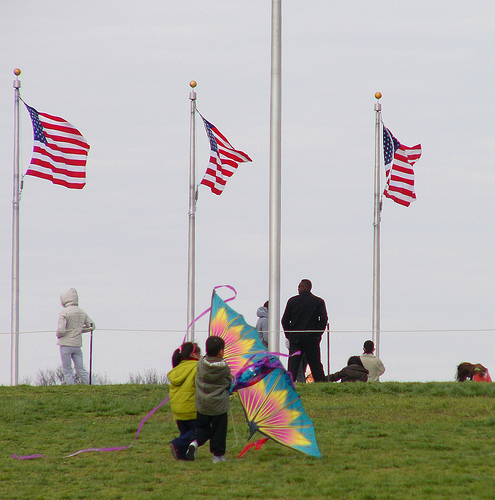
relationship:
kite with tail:
[210, 280, 330, 459] [9, 284, 238, 462]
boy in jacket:
[186, 335, 236, 468] [172, 283, 257, 418]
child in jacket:
[166, 342, 202, 460] [199, 360, 228, 430]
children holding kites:
[166, 335, 233, 465] [203, 300, 331, 461]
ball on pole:
[9, 65, 26, 79] [3, 79, 30, 383]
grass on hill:
[2, 386, 494, 498] [7, 380, 492, 497]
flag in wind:
[380, 119, 422, 208] [7, 59, 439, 223]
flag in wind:
[194, 108, 255, 196] [7, 59, 439, 223]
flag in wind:
[23, 104, 90, 189] [7, 59, 439, 223]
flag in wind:
[371, 116, 425, 208] [336, 73, 430, 234]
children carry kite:
[166, 335, 233, 465] [205, 289, 334, 458]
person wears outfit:
[43, 287, 105, 382] [53, 286, 98, 379]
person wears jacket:
[281, 279, 329, 381] [281, 295, 326, 339]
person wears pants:
[281, 279, 329, 381] [287, 330, 323, 379]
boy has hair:
[186, 335, 232, 463] [205, 337, 223, 356]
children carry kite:
[166, 335, 233, 465] [207, 271, 323, 456]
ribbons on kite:
[231, 344, 306, 392] [190, 276, 358, 488]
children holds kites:
[132, 285, 342, 462] [212, 251, 365, 460]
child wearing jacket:
[168, 342, 199, 458] [169, 362, 197, 418]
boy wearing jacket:
[186, 335, 232, 463] [197, 357, 233, 414]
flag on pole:
[194, 102, 256, 196] [186, 78, 194, 339]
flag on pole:
[22, 96, 92, 197] [12, 66, 21, 388]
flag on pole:
[380, 119, 422, 208] [368, 88, 379, 351]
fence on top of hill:
[80, 321, 467, 385] [12, 367, 493, 480]